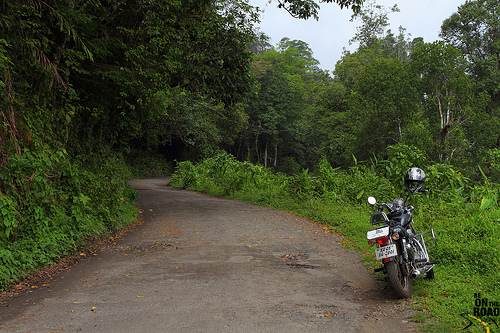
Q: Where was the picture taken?
A: On a country road.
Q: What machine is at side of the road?
A: A motorcycle.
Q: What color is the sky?
A: Light blue.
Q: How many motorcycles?
A: One.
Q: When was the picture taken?
A: In the afternoon.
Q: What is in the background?
A: Trees.